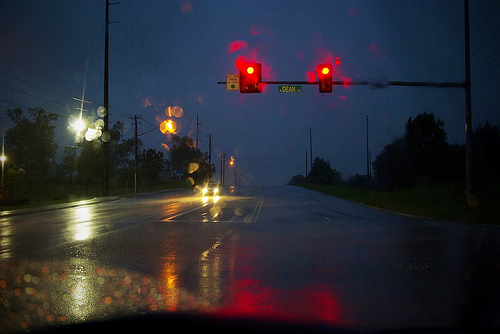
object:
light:
[247, 67, 254, 74]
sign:
[226, 74, 239, 90]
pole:
[395, 80, 467, 85]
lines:
[109, 20, 121, 23]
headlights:
[213, 196, 221, 203]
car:
[201, 183, 220, 197]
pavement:
[15, 222, 225, 283]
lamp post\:
[66, 105, 111, 148]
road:
[195, 227, 240, 303]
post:
[159, 159, 169, 172]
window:
[208, 184, 216, 187]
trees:
[0, 105, 58, 177]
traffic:
[239, 63, 333, 93]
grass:
[0, 199, 69, 210]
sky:
[351, 20, 388, 91]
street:
[262, 187, 500, 334]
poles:
[102, 23, 109, 197]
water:
[132, 50, 179, 100]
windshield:
[0, 24, 264, 226]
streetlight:
[159, 106, 183, 135]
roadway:
[162, 196, 331, 223]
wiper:
[185, 307, 200, 317]